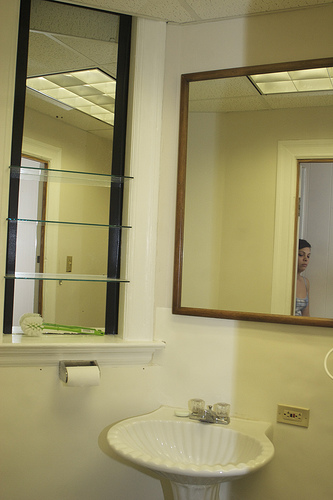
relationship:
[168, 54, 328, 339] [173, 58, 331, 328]
mirror has frame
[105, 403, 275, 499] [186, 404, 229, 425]
sink has faucet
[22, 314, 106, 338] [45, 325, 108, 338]
bathroom brush has handle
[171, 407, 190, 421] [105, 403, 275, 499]
soap on top of sink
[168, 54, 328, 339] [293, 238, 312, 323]
mirror has reflection of woman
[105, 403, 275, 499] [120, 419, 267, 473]
sink has scalloped bowl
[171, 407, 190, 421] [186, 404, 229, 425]
soap next to faucet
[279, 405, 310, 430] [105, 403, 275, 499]
electric outlet next to sink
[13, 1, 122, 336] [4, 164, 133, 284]
mirror has glass shelves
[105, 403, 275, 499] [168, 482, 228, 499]
sink has pedestal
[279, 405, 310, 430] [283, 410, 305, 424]
electric outlet has double socket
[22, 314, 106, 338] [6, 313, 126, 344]
bathroom brush on shelf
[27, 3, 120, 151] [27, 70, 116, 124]
ceiling has light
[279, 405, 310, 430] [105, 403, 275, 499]
electric outlet near sink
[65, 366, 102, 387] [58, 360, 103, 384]
toilet paper hangs from holder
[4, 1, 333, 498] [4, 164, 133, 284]
bathroom has shelves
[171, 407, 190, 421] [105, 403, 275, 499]
soap sitting on top of sink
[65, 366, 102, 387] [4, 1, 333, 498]
toilet paper hangs from wall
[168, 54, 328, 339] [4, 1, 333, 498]
mirror hangs from wall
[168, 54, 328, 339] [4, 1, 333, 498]
mirror in bathroom